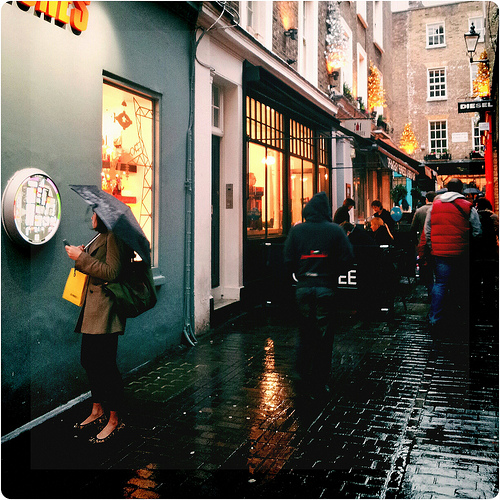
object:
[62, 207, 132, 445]
woman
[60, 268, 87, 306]
bag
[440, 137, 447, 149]
window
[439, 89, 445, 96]
window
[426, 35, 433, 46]
window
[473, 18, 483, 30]
window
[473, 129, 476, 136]
window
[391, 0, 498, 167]
building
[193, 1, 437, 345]
building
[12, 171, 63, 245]
map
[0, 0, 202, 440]
building